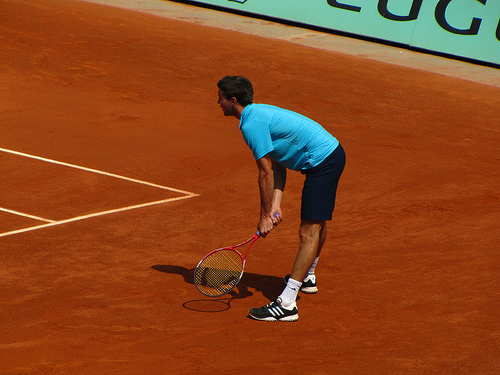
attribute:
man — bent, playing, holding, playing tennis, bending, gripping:
[185, 77, 370, 350]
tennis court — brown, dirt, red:
[21, 29, 171, 332]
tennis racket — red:
[182, 229, 268, 304]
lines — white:
[80, 208, 105, 231]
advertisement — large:
[395, 6, 484, 62]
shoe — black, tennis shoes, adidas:
[247, 294, 290, 327]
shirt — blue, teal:
[243, 98, 323, 172]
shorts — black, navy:
[298, 156, 344, 221]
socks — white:
[276, 274, 303, 307]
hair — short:
[215, 72, 255, 103]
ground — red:
[96, 67, 150, 143]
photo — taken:
[7, 0, 484, 375]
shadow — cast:
[141, 258, 183, 281]